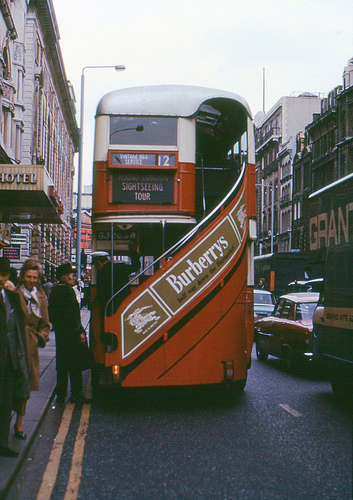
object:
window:
[288, 160, 291, 171]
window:
[282, 187, 284, 196]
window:
[264, 155, 267, 167]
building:
[251, 89, 326, 256]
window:
[4, 105, 10, 146]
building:
[0, 1, 83, 319]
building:
[291, 58, 353, 250]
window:
[288, 182, 290, 192]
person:
[47, 260, 96, 404]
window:
[269, 181, 272, 204]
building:
[276, 134, 296, 254]